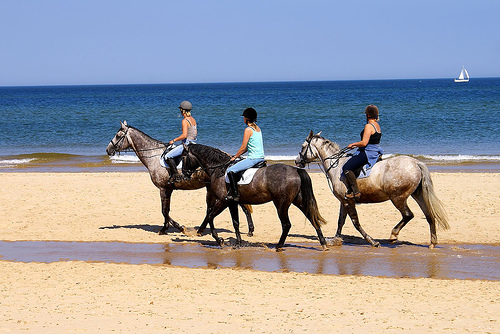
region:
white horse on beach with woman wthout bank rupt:
[294, 103, 453, 249]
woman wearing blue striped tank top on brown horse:
[179, 99, 334, 258]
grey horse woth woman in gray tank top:
[108, 117, 238, 230]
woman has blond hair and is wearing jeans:
[163, 135, 204, 166]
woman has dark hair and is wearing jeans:
[222, 154, 271, 187]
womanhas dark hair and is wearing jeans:
[238, 123, 270, 158]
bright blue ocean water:
[13, 58, 498, 145]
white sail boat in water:
[448, 65, 479, 89]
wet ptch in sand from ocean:
[2, 219, 499, 276]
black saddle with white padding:
[220, 156, 272, 190]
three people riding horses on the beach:
[105, 98, 451, 249]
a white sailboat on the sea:
[452, 65, 469, 81]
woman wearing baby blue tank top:
[243, 123, 263, 156]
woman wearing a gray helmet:
[177, 100, 192, 110]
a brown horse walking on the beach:
[181, 136, 328, 253]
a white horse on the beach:
[295, 127, 450, 249]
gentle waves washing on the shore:
[3, 150, 498, 165]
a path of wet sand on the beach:
[1, 236, 497, 281]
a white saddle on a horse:
[225, 167, 258, 185]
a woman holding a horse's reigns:
[304, 142, 354, 179]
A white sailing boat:
[446, 54, 475, 94]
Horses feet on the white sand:
[137, 215, 205, 242]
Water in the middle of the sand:
[15, 218, 113, 298]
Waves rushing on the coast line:
[426, 147, 499, 184]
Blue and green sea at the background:
[25, 90, 87, 135]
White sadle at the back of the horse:
[238, 161, 270, 189]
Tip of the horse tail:
[436, 212, 463, 234]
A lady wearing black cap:
[240, 102, 262, 130]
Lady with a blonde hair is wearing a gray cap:
[170, 95, 200, 120]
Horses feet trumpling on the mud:
[199, 230, 285, 257]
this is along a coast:
[12, 43, 453, 305]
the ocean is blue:
[33, 94, 115, 132]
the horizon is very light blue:
[27, 12, 385, 79]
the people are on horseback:
[95, 105, 462, 250]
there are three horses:
[113, 105, 462, 272]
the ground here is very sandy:
[6, 205, 161, 320]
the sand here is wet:
[23, 231, 111, 275]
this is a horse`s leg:
[342, 189, 381, 257]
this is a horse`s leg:
[391, 198, 417, 251]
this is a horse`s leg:
[417, 192, 450, 251]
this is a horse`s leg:
[153, 189, 185, 238]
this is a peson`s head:
[227, 94, 267, 132]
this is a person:
[159, 90, 196, 174]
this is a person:
[218, 101, 265, 193]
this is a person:
[332, 92, 388, 204]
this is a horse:
[290, 125, 451, 247]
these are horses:
[97, 119, 455, 264]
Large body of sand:
[86, 288, 187, 328]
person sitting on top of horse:
[224, 106, 264, 201]